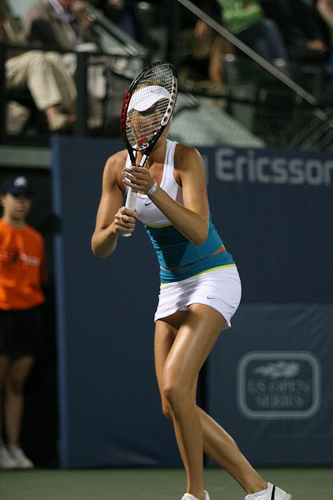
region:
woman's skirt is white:
[137, 261, 238, 322]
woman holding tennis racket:
[82, 66, 202, 201]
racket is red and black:
[106, 60, 184, 235]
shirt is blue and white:
[114, 141, 223, 257]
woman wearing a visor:
[113, 83, 195, 118]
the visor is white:
[113, 76, 178, 112]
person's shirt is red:
[0, 222, 48, 308]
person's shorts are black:
[2, 299, 51, 366]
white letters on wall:
[208, 149, 332, 193]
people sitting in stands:
[0, 1, 331, 157]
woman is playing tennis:
[90, 78, 292, 499]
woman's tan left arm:
[119, 142, 209, 245]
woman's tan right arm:
[91, 149, 138, 258]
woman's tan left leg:
[162, 303, 225, 498]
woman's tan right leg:
[154, 309, 267, 493]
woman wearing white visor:
[126, 85, 171, 114]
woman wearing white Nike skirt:
[154, 267, 241, 330]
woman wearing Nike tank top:
[123, 138, 236, 285]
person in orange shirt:
[0, 176, 47, 468]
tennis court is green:
[0, 469, 332, 498]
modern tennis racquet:
[110, 58, 187, 241]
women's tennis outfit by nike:
[93, 132, 258, 332]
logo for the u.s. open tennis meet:
[221, 337, 331, 429]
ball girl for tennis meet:
[0, 155, 64, 480]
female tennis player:
[68, 47, 295, 497]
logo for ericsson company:
[207, 129, 331, 184]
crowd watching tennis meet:
[2, 4, 327, 139]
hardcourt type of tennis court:
[3, 473, 331, 496]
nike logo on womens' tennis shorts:
[197, 287, 219, 309]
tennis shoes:
[169, 484, 308, 498]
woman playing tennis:
[85, 64, 297, 498]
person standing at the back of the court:
[2, 170, 69, 475]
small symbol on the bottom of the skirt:
[202, 293, 214, 304]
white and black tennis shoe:
[241, 480, 292, 499]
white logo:
[235, 349, 325, 424]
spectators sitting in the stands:
[2, 0, 332, 154]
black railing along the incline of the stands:
[118, 0, 316, 141]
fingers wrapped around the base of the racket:
[112, 206, 143, 237]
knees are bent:
[144, 370, 201, 433]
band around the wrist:
[141, 178, 163, 201]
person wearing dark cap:
[7, 176, 36, 200]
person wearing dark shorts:
[0, 303, 43, 355]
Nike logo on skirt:
[205, 296, 214, 300]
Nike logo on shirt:
[144, 196, 153, 207]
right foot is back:
[243, 481, 290, 499]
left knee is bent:
[162, 380, 191, 399]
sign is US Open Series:
[238, 352, 322, 419]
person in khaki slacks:
[1, 50, 77, 130]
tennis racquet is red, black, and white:
[119, 60, 178, 237]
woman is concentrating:
[89, 78, 292, 499]